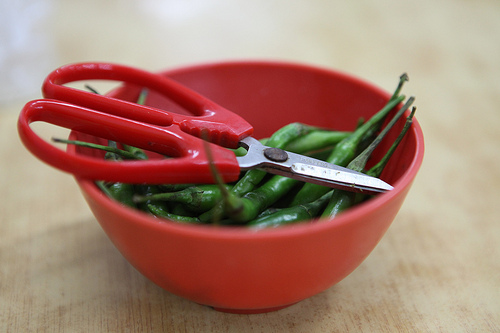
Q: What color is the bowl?
A: Red.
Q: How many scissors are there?
A: One.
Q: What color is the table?
A: Brown.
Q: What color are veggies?
A: Green.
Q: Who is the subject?
A: The bowl.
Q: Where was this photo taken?
A: Near food.